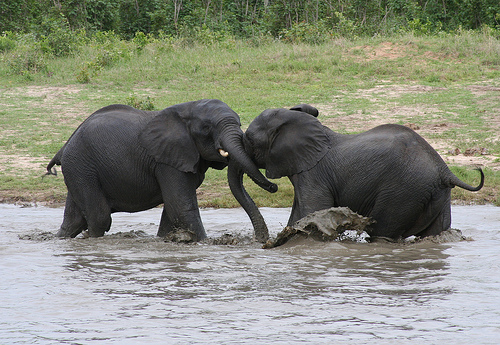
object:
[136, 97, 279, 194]
head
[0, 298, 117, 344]
water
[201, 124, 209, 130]
eye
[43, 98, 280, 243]
elephant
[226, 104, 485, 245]
elephant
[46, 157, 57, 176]
tail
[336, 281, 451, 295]
wave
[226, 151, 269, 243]
trunk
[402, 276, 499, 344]
water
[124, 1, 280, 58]
trees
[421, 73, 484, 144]
ground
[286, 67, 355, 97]
grass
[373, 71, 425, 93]
dirt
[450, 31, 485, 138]
land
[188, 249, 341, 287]
water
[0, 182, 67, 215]
bank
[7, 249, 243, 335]
river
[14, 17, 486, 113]
land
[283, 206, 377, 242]
splash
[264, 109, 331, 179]
ear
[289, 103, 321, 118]
ear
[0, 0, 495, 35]
bushes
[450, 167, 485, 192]
tail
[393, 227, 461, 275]
water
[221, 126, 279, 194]
trunk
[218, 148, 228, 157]
elephant's tusk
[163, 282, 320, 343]
water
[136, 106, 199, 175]
ear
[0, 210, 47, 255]
water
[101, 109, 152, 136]
back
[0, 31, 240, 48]
grass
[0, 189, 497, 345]
lake